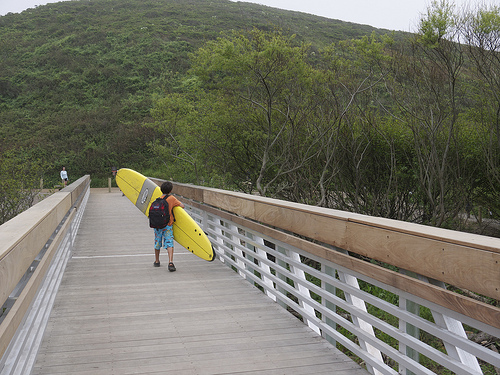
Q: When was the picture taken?
A: Daytime.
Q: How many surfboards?
A: One.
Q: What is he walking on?
A: Bridge.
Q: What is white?
A: Railings.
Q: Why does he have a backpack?
A: For his stuff.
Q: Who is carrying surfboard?
A: Boy.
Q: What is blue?
A: Shorts.